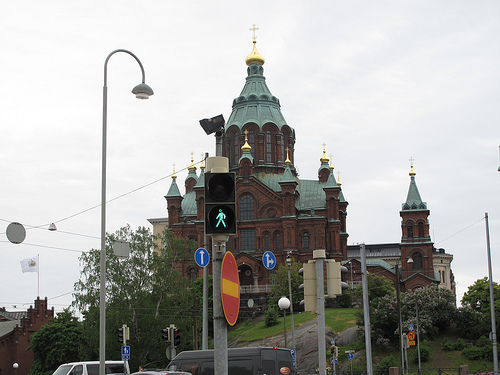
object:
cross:
[245, 23, 266, 43]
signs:
[193, 249, 278, 271]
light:
[133, 89, 154, 104]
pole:
[91, 48, 117, 373]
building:
[152, 2, 457, 298]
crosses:
[167, 10, 428, 177]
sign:
[215, 251, 248, 332]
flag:
[15, 251, 41, 281]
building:
[4, 293, 59, 369]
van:
[167, 342, 299, 373]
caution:
[223, 253, 247, 320]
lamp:
[277, 288, 293, 315]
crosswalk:
[202, 206, 240, 242]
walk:
[216, 207, 230, 231]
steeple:
[245, 15, 273, 73]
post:
[281, 310, 291, 356]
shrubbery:
[365, 287, 498, 369]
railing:
[239, 284, 274, 294]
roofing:
[219, 71, 307, 128]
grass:
[327, 300, 360, 330]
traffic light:
[159, 318, 180, 357]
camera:
[198, 113, 233, 143]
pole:
[213, 132, 225, 163]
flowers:
[420, 291, 429, 304]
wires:
[2, 224, 186, 262]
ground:
[12, 370, 34, 374]